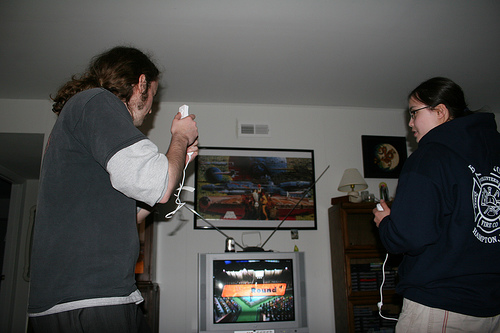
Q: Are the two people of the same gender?
A: No, they are both male and female.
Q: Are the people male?
A: No, they are both male and female.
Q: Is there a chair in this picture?
A: No, there are no chairs.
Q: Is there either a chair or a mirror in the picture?
A: No, there are no chairs or mirrors.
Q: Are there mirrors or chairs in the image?
A: No, there are no chairs or mirrors.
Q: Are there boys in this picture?
A: No, there are no boys.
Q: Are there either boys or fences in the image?
A: No, there are no boys or fences.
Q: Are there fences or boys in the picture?
A: No, there are no boys or fences.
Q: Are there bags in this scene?
A: No, there are no bags.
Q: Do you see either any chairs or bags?
A: No, there are no bags or chairs.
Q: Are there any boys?
A: No, there are no boys.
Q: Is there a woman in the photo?
A: Yes, there is a woman.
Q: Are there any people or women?
A: Yes, there is a woman.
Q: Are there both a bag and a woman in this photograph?
A: No, there is a woman but no bags.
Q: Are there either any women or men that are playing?
A: Yes, the woman is playing.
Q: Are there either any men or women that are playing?
A: Yes, the woman is playing.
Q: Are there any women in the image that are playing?
A: Yes, there is a woman that is playing.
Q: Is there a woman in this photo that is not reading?
A: Yes, there is a woman that is playing.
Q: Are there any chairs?
A: No, there are no chairs.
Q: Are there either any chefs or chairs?
A: No, there are no chairs or chefs.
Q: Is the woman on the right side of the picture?
A: Yes, the woman is on the right of the image.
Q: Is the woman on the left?
A: No, the woman is on the right of the image.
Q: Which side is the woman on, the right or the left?
A: The woman is on the right of the image.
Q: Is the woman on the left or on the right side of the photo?
A: The woman is on the right of the image.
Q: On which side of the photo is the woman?
A: The woman is on the right of the image.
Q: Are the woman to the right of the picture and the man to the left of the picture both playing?
A: Yes, both the woman and the man are playing.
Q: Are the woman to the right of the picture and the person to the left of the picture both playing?
A: Yes, both the woman and the man are playing.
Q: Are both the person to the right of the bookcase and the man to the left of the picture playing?
A: Yes, both the woman and the man are playing.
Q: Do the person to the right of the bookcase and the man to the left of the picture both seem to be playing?
A: Yes, both the woman and the man are playing.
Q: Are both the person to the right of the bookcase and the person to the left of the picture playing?
A: Yes, both the woman and the man are playing.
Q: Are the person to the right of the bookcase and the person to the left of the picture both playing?
A: Yes, both the woman and the man are playing.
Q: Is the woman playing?
A: Yes, the woman is playing.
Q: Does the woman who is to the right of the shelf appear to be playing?
A: Yes, the woman is playing.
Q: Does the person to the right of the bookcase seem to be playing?
A: Yes, the woman is playing.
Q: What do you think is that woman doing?
A: The woman is playing.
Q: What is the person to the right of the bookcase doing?
A: The woman is playing.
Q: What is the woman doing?
A: The woman is playing.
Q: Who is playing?
A: The woman is playing.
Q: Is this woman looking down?
A: No, the woman is playing.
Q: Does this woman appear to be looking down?
A: No, the woman is playing.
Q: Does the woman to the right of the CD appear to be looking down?
A: No, the woman is playing.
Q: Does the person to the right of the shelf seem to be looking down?
A: No, the woman is playing.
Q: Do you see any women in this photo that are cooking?
A: No, there is a woman but she is playing.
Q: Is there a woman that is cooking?
A: No, there is a woman but she is playing.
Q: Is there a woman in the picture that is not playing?
A: No, there is a woman but she is playing.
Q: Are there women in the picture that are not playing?
A: No, there is a woman but she is playing.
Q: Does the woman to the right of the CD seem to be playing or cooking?
A: The woman is playing.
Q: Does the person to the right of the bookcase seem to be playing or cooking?
A: The woman is playing.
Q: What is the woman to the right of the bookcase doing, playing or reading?
A: The woman is playing.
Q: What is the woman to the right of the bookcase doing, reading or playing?
A: The woman is playing.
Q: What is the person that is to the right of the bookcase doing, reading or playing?
A: The woman is playing.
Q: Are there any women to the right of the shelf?
A: Yes, there is a woman to the right of the shelf.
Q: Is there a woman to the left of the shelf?
A: No, the woman is to the right of the shelf.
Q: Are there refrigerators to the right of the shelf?
A: No, there is a woman to the right of the shelf.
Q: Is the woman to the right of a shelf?
A: Yes, the woman is to the right of a shelf.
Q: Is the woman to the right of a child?
A: No, the woman is to the right of a shelf.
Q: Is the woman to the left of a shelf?
A: No, the woman is to the right of a shelf.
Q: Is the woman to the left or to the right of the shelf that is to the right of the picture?
A: The woman is to the right of the shelf.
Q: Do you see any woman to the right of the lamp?
A: Yes, there is a woman to the right of the lamp.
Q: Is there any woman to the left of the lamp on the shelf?
A: No, the woman is to the right of the lamp.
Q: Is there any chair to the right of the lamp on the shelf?
A: No, there is a woman to the right of the lamp.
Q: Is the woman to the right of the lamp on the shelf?
A: Yes, the woman is to the right of the lamp.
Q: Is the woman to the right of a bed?
A: No, the woman is to the right of the lamp.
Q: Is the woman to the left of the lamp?
A: No, the woman is to the right of the lamp.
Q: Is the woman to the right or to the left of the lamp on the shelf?
A: The woman is to the right of the lamp.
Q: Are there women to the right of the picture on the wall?
A: Yes, there is a woman to the right of the picture.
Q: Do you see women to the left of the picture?
A: No, the woman is to the right of the picture.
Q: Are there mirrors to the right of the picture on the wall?
A: No, there is a woman to the right of the picture.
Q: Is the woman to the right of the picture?
A: Yes, the woman is to the right of the picture.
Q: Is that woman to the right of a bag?
A: No, the woman is to the right of the picture.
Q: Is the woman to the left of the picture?
A: No, the woman is to the right of the picture.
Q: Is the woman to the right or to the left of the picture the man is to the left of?
A: The woman is to the right of the picture.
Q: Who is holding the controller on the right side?
A: The woman is holding the controller.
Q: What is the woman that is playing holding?
A: The woman is holding the controller.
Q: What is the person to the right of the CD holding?
A: The woman is holding the controller.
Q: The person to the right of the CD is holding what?
A: The woman is holding the controller.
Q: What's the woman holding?
A: The woman is holding the controller.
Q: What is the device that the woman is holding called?
A: The device is a controller.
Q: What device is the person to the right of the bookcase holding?
A: The woman is holding the controller.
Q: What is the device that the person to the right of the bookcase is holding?
A: The device is a controller.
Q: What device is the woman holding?
A: The woman is holding the controller.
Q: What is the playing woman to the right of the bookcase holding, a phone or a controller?
A: The woman is holding a controller.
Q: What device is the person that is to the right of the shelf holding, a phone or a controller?
A: The woman is holding a controller.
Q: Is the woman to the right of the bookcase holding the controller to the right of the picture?
A: Yes, the woman is holding the controller.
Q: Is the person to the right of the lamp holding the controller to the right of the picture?
A: Yes, the woman is holding the controller.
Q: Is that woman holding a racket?
A: No, the woman is holding the controller.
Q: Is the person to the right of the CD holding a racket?
A: No, the woman is holding the controller.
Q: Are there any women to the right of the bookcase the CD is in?
A: Yes, there is a woman to the right of the bookcase.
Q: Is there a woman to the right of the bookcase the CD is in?
A: Yes, there is a woman to the right of the bookcase.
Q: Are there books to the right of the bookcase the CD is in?
A: No, there is a woman to the right of the bookcase.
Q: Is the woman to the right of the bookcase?
A: Yes, the woman is to the right of the bookcase.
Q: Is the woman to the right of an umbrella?
A: No, the woman is to the right of the bookcase.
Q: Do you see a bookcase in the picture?
A: Yes, there is a bookcase.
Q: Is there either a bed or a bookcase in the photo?
A: Yes, there is a bookcase.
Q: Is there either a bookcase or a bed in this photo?
A: Yes, there is a bookcase.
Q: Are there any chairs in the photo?
A: No, there are no chairs.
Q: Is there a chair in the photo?
A: No, there are no chairs.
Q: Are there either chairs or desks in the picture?
A: No, there are no chairs or desks.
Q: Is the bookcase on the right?
A: Yes, the bookcase is on the right of the image.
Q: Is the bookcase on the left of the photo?
A: No, the bookcase is on the right of the image.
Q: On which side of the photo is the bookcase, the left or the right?
A: The bookcase is on the right of the image.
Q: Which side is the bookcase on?
A: The bookcase is on the right of the image.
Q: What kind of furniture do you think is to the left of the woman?
A: The piece of furniture is a bookcase.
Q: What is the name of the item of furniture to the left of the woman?
A: The piece of furniture is a bookcase.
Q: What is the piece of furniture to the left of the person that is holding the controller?
A: The piece of furniture is a bookcase.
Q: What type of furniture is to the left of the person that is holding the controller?
A: The piece of furniture is a bookcase.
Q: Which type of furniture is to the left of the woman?
A: The piece of furniture is a bookcase.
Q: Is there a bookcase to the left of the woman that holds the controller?
A: Yes, there is a bookcase to the left of the woman.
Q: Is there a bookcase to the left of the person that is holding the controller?
A: Yes, there is a bookcase to the left of the woman.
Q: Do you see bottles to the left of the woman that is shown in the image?
A: No, there is a bookcase to the left of the woman.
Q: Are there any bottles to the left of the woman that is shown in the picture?
A: No, there is a bookcase to the left of the woman.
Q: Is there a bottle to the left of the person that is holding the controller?
A: No, there is a bookcase to the left of the woman.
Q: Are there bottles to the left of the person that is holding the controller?
A: No, there is a bookcase to the left of the woman.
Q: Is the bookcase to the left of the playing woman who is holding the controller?
A: Yes, the bookcase is to the left of the woman.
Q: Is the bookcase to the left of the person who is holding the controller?
A: Yes, the bookcase is to the left of the woman.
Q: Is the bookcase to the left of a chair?
A: No, the bookcase is to the left of the woman.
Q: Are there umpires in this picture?
A: No, there are no umpires.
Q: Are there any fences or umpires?
A: No, there are no umpires or fences.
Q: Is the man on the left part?
A: Yes, the man is on the left of the image.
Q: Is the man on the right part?
A: No, the man is on the left of the image.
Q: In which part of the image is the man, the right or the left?
A: The man is on the left of the image.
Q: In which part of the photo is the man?
A: The man is on the left of the image.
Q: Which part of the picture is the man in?
A: The man is on the left of the image.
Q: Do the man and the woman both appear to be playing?
A: Yes, both the man and the woman are playing.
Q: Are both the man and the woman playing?
A: Yes, both the man and the woman are playing.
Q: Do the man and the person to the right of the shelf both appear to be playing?
A: Yes, both the man and the woman are playing.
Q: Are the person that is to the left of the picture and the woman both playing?
A: Yes, both the man and the woman are playing.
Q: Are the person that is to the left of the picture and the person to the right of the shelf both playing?
A: Yes, both the man and the woman are playing.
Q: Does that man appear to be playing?
A: Yes, the man is playing.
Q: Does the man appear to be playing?
A: Yes, the man is playing.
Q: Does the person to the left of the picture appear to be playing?
A: Yes, the man is playing.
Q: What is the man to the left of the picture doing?
A: The man is playing.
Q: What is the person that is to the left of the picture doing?
A: The man is playing.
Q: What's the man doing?
A: The man is playing.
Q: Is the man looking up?
A: No, the man is playing.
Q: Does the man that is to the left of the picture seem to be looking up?
A: No, the man is playing.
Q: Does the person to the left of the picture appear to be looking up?
A: No, the man is playing.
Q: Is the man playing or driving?
A: The man is playing.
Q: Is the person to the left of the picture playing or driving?
A: The man is playing.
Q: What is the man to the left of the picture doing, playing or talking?
A: The man is playing.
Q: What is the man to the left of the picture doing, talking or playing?
A: The man is playing.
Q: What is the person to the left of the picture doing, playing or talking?
A: The man is playing.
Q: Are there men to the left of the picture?
A: Yes, there is a man to the left of the picture.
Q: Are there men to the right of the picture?
A: No, the man is to the left of the picture.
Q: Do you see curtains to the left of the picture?
A: No, there is a man to the left of the picture.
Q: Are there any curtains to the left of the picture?
A: No, there is a man to the left of the picture.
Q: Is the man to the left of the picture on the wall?
A: Yes, the man is to the left of the picture.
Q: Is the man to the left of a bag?
A: No, the man is to the left of the picture.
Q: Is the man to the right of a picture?
A: No, the man is to the left of a picture.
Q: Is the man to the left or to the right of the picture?
A: The man is to the left of the picture.